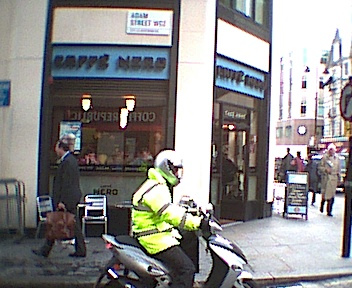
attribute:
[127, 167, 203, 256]
jacket — bright yellow, yellow, fluorescent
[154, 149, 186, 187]
helmet — silver, shiny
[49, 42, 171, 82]
sign — blue, black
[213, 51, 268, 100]
sign — blue, black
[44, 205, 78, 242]
bag — brown, small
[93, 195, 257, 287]
motorcycle — silver, small, nice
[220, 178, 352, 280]
sidewalk — wet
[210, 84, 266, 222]
doorframe — glass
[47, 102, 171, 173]
windows — large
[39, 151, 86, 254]
suit — black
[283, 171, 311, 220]
menu — small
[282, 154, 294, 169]
jacket — black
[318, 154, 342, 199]
trench coat — brown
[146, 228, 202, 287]
pants — black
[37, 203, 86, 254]
pants — black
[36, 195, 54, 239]
chair — white, empty, iron, nice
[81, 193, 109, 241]
chair — white, empty, iron, nice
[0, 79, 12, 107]
sign — blue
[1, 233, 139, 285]
sidewalk — wet